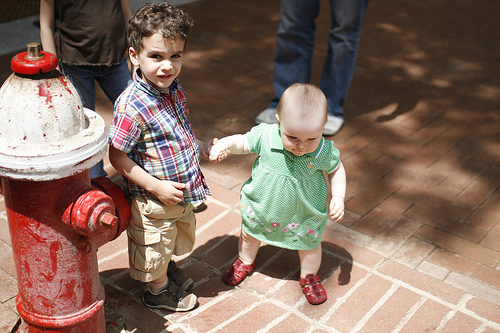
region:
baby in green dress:
[212, 80, 349, 307]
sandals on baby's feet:
[219, 258, 331, 308]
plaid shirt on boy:
[107, 63, 213, 205]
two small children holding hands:
[107, 1, 352, 313]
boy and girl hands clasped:
[199, 133, 235, 164]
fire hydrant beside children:
[0, 39, 132, 331]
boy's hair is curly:
[126, 1, 197, 50]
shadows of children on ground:
[176, 229, 367, 300]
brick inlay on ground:
[374, 149, 487, 261]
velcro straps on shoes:
[162, 262, 196, 300]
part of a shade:
[386, 91, 431, 171]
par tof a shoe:
[310, 290, 329, 322]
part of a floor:
[386, 220, 419, 265]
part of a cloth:
[307, 214, 322, 233]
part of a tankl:
[46, 185, 100, 286]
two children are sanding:
[104, 0, 354, 330]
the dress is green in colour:
[240, 125, 345, 254]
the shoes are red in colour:
[221, 254, 337, 299]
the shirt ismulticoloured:
[109, 74, 211, 205]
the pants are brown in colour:
[133, 193, 205, 275]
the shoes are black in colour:
[138, 273, 214, 313]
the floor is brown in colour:
[326, 252, 484, 329]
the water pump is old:
[5, 45, 146, 330]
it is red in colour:
[1, 14, 129, 331]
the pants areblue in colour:
[269, 5, 358, 80]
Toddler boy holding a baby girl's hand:
[108, 2, 395, 313]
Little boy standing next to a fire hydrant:
[1, 1, 229, 332]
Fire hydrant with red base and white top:
[1, 43, 130, 331]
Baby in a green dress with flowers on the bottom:
[211, 82, 348, 304]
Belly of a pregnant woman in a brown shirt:
[53, 0, 127, 65]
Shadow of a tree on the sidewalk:
[140, 2, 496, 239]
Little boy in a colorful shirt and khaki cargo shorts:
[106, 1, 214, 316]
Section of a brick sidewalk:
[345, 154, 499, 331]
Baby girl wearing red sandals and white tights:
[205, 79, 347, 310]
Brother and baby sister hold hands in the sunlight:
[105, 2, 350, 312]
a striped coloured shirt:
[127, 70, 204, 188]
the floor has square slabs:
[193, 307, 265, 332]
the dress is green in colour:
[251, 144, 316, 248]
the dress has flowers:
[244, 185, 324, 268]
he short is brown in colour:
[138, 175, 199, 271]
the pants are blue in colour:
[275, 31, 342, 61]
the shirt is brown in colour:
[61, 6, 105, 42]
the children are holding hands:
[193, 120, 234, 181]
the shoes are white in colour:
[323, 103, 348, 131]